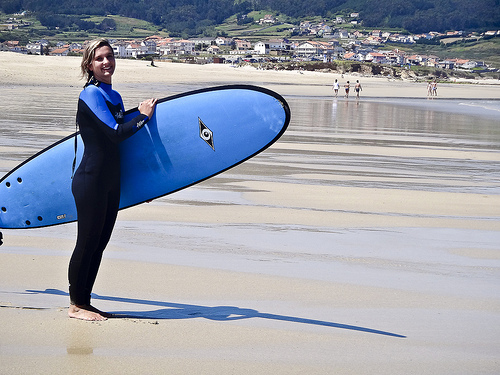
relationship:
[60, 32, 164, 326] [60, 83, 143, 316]
lady in wet suit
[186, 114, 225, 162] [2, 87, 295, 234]
logo on board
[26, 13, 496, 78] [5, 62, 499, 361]
buildings are on beach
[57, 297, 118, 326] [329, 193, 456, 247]
feet in sand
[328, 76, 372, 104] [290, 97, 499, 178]
people in water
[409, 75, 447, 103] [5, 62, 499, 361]
people walking on beach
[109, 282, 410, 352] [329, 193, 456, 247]
shadow in sand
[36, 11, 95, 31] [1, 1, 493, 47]
tree in horizon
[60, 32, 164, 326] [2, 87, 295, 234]
lady holding surfboard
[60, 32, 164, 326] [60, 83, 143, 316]
lady wearing wet suit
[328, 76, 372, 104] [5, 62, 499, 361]
people running across beach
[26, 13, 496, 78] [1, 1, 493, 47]
buildings in horizon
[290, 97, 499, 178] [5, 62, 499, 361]
water across beach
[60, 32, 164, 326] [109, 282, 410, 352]
lady casting shadow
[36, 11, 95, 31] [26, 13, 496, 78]
tree behind buildings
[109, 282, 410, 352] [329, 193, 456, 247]
shadow on sand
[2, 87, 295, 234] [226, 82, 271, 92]
board has black border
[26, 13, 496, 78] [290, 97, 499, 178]
buildings in front of water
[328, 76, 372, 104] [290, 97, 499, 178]
people in front of water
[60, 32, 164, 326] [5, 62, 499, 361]
lady on beach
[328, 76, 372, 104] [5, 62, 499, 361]
people walking on beach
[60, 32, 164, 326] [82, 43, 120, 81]
lady has head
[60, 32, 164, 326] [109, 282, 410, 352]
lady has shadow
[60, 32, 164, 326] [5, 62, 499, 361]
lady standing on beach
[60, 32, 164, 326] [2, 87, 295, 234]
lady holding board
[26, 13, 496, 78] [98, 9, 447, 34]
buildings in mountains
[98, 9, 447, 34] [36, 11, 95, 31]
mountains has lots of tree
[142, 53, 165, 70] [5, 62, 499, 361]
person sitting on beach